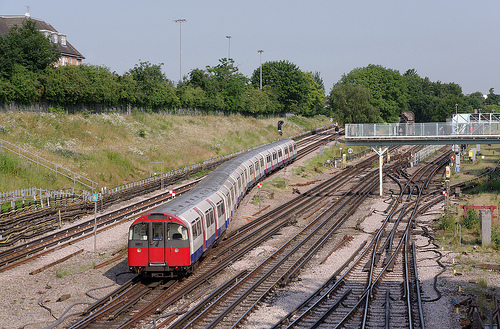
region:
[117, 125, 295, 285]
a commuter train on the tracks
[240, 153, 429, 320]
several sets of train tracks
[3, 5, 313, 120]
trees line a fence above train tracks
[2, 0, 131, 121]
a house behind some trees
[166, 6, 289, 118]
three light posts with lights on top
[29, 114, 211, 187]
a mixture of green and yellow grass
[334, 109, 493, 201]
a platform above train tracks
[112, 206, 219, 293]
a red and silver train car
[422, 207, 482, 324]
small yellow flags along train tracks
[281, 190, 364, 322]
gravel between train tracks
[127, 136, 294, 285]
A long train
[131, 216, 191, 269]
The front of the train is red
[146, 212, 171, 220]
A sign on the front of the train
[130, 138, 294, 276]
The train cars are silver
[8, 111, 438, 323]
A row of train tracks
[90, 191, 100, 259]
A small metal pole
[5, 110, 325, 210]
green and brown grass beside the tracks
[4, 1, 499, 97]
the sky is a hazy blue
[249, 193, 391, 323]
small gravel between the tracks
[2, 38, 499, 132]
A row of green trees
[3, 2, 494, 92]
the blue sky above the train tracks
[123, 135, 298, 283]
a long train on the track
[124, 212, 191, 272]
the red front of the train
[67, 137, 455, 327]
multiple train tracks next to a hill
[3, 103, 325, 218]
the hill next to the trees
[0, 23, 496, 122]
a long ling of green trees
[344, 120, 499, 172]
a small bridge next to some of the trees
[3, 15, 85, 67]
a building behind the trees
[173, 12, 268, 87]
a small row of street lights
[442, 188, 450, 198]
a little red sign on the side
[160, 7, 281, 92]
Tall light posts in the sky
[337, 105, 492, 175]
Platform over railroad tracks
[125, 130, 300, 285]
Silver commuter train with red front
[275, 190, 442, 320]
Empty railroad tracks in the dirt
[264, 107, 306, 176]
Railway signal behind train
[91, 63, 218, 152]
Grassy field on hill below trees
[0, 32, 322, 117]
Trees along a fence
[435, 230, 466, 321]
Yellow markers on the ground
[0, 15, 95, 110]
House behind a trees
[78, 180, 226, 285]
Blue sign to the left of train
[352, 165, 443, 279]
intersection on the train tracks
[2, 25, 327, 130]
series of trees lining a fence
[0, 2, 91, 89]
house overlooking a train station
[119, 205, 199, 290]
red front of train car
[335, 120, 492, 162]
elevated walking area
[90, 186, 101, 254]
small blue sign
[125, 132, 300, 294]
red, blue and grey train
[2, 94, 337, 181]
hill next to railroad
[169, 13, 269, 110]
three light posts behind a fence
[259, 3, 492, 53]
patch of blue sky